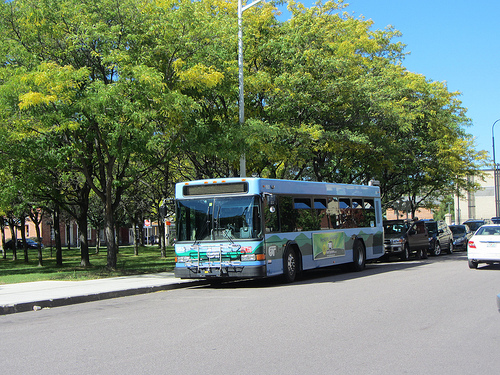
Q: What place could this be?
A: It is a road.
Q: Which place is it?
A: It is a road.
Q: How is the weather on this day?
A: It is clear.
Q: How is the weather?
A: It is clear.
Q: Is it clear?
A: Yes, it is clear.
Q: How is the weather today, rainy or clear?
A: It is clear.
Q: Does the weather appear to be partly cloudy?
A: No, it is clear.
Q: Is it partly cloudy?
A: No, it is clear.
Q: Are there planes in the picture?
A: No, there are no planes.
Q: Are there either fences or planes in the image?
A: No, there are no planes or fences.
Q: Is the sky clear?
A: Yes, the sky is clear.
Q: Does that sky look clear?
A: Yes, the sky is clear.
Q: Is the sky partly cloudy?
A: No, the sky is clear.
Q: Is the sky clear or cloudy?
A: The sky is clear.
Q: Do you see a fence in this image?
A: No, there are no fences.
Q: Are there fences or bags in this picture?
A: No, there are no fences or bags.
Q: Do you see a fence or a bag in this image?
A: No, there are no fences or bags.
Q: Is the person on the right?
A: Yes, the person is on the right of the image.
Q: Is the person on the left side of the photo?
A: No, the person is on the right of the image.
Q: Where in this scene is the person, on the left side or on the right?
A: The person is on the right of the image.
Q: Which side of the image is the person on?
A: The person is on the right of the image.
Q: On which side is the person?
A: The person is on the right of the image.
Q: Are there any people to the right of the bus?
A: Yes, there is a person to the right of the bus.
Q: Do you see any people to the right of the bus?
A: Yes, there is a person to the right of the bus.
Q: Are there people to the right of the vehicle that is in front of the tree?
A: Yes, there is a person to the right of the bus.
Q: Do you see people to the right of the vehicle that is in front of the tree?
A: Yes, there is a person to the right of the bus.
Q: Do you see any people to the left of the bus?
A: No, the person is to the right of the bus.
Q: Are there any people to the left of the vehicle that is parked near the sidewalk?
A: No, the person is to the right of the bus.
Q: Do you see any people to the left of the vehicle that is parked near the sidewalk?
A: No, the person is to the right of the bus.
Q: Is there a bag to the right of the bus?
A: No, there is a person to the right of the bus.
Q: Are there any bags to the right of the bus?
A: No, there is a person to the right of the bus.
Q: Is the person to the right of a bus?
A: Yes, the person is to the right of a bus.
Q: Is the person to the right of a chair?
A: No, the person is to the right of a bus.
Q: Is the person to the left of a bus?
A: No, the person is to the right of a bus.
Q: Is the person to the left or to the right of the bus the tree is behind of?
A: The person is to the right of the bus.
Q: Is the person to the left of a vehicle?
A: Yes, the person is to the left of a vehicle.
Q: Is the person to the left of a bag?
A: No, the person is to the left of a vehicle.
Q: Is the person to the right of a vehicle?
A: No, the person is to the left of a vehicle.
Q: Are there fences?
A: No, there are no fences.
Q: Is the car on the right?
A: Yes, the car is on the right of the image.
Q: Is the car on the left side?
A: No, the car is on the right of the image.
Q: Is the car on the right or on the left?
A: The car is on the right of the image.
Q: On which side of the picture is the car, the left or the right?
A: The car is on the right of the image.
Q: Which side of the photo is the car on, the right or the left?
A: The car is on the right of the image.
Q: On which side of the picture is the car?
A: The car is on the right of the image.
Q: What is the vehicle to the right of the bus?
A: The vehicle is a car.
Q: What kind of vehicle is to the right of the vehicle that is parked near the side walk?
A: The vehicle is a car.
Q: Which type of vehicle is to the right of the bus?
A: The vehicle is a car.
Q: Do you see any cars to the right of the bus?
A: Yes, there is a car to the right of the bus.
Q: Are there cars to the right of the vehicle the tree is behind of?
A: Yes, there is a car to the right of the bus.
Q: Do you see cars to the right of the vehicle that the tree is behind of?
A: Yes, there is a car to the right of the bus.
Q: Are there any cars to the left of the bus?
A: No, the car is to the right of the bus.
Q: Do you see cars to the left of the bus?
A: No, the car is to the right of the bus.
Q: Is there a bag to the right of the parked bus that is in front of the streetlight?
A: No, there is a car to the right of the bus.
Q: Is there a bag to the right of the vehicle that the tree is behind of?
A: No, there is a car to the right of the bus.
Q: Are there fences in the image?
A: No, there are no fences.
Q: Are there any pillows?
A: No, there are no pillows.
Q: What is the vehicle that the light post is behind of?
A: The vehicle is a bus.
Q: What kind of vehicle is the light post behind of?
A: The light post is behind the bus.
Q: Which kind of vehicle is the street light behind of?
A: The light post is behind the bus.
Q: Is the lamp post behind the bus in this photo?
A: Yes, the lamp post is behind the bus.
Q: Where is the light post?
A: The light post is on the side walk.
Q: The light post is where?
A: The light post is on the side walk.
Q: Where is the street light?
A: The light post is on the side walk.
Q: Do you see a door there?
A: Yes, there is a door.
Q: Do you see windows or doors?
A: Yes, there is a door.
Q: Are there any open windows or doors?
A: Yes, there is an open door.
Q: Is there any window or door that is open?
A: Yes, the door is open.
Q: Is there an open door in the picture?
A: Yes, there is an open door.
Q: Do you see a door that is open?
A: Yes, there is an open door.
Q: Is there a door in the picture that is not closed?
A: Yes, there is a open door.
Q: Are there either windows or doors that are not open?
A: No, there is a door but it is open.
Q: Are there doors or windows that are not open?
A: No, there is a door but it is open.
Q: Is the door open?
A: Yes, the door is open.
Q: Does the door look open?
A: Yes, the door is open.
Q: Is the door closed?
A: No, the door is open.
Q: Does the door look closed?
A: No, the door is open.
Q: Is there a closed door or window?
A: No, there is a door but it is open.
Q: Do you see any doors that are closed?
A: No, there is a door but it is open.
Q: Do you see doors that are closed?
A: No, there is a door but it is open.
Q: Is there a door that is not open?
A: No, there is a door but it is open.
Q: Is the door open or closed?
A: The door is open.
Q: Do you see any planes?
A: No, there are no planes.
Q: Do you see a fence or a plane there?
A: No, there are no airplanes or fences.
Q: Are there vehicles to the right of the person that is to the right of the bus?
A: Yes, there is a vehicle to the right of the person.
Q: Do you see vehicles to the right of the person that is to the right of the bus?
A: Yes, there is a vehicle to the right of the person.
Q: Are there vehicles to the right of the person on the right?
A: Yes, there is a vehicle to the right of the person.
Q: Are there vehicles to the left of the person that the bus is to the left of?
A: No, the vehicle is to the right of the person.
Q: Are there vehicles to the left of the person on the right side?
A: No, the vehicle is to the right of the person.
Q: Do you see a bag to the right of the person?
A: No, there is a vehicle to the right of the person.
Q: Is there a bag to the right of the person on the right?
A: No, there is a vehicle to the right of the person.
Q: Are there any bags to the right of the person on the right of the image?
A: No, there is a vehicle to the right of the person.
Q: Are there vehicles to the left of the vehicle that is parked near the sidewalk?
A: No, the vehicle is to the right of the bus.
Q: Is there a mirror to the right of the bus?
A: No, there is a vehicle to the right of the bus.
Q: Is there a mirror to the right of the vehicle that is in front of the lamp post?
A: No, there is a vehicle to the right of the bus.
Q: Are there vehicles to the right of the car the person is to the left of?
A: Yes, there is a vehicle to the right of the car.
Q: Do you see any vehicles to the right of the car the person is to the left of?
A: Yes, there is a vehicle to the right of the car.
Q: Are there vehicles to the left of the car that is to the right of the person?
A: No, the vehicle is to the right of the car.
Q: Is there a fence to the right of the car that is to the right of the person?
A: No, there is a vehicle to the right of the car.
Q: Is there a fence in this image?
A: No, there are no fences.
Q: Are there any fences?
A: No, there are no fences.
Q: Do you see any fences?
A: No, there are no fences.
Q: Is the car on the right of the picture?
A: Yes, the car is on the right of the image.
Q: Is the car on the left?
A: No, the car is on the right of the image.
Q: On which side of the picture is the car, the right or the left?
A: The car is on the right of the image.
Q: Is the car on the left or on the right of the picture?
A: The car is on the right of the image.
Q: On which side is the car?
A: The car is on the right of the image.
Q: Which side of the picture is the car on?
A: The car is on the right of the image.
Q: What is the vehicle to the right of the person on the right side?
A: The vehicle is a car.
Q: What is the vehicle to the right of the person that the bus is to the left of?
A: The vehicle is a car.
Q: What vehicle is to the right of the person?
A: The vehicle is a car.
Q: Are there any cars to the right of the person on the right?
A: Yes, there is a car to the right of the person.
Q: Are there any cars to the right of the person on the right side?
A: Yes, there is a car to the right of the person.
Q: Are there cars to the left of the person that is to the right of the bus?
A: No, the car is to the right of the person.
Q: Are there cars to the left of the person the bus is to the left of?
A: No, the car is to the right of the person.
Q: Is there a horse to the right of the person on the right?
A: No, there is a car to the right of the person.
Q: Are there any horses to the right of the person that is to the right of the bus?
A: No, there is a car to the right of the person.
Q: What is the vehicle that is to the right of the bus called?
A: The vehicle is a car.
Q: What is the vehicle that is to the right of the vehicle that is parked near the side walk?
A: The vehicle is a car.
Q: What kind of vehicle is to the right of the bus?
A: The vehicle is a car.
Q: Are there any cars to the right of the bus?
A: Yes, there is a car to the right of the bus.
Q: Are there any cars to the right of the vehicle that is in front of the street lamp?
A: Yes, there is a car to the right of the bus.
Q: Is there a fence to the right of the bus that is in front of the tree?
A: No, there is a car to the right of the bus.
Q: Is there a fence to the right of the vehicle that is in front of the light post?
A: No, there is a car to the right of the bus.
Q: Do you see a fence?
A: No, there are no fences.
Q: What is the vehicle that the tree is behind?
A: The vehicle is a bus.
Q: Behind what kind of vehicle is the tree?
A: The tree is behind the bus.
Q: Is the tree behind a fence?
A: No, the tree is behind a bus.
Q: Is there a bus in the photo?
A: Yes, there is a bus.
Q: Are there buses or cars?
A: Yes, there is a bus.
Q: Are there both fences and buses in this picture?
A: No, there is a bus but no fences.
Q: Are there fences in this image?
A: No, there are no fences.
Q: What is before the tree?
A: The bus is in front of the tree.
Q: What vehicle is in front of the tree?
A: The vehicle is a bus.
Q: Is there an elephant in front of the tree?
A: No, there is a bus in front of the tree.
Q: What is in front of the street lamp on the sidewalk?
A: The bus is in front of the lamp post.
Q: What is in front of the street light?
A: The bus is in front of the lamp post.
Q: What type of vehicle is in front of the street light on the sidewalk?
A: The vehicle is a bus.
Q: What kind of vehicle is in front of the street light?
A: The vehicle is a bus.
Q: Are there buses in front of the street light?
A: Yes, there is a bus in front of the street light.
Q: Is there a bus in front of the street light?
A: Yes, there is a bus in front of the street light.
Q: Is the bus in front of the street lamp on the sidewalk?
A: Yes, the bus is in front of the street light.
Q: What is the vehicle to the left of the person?
A: The vehicle is a bus.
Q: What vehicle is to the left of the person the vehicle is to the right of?
A: The vehicle is a bus.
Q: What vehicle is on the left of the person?
A: The vehicle is a bus.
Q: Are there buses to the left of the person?
A: Yes, there is a bus to the left of the person.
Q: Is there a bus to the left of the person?
A: Yes, there is a bus to the left of the person.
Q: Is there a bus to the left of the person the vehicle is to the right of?
A: Yes, there is a bus to the left of the person.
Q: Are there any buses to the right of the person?
A: No, the bus is to the left of the person.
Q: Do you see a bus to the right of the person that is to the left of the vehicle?
A: No, the bus is to the left of the person.